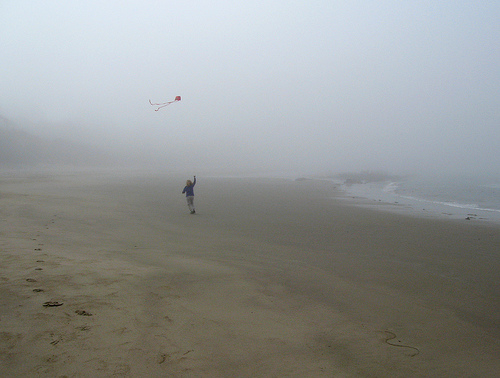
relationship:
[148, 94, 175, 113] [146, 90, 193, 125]
tail on kite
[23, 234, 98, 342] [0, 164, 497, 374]
marks on sand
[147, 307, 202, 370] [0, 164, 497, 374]
marks on sand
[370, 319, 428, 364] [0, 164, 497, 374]
marks on sand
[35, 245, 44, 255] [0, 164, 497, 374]
footstep in sand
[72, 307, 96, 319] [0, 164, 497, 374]
foot imprints in sand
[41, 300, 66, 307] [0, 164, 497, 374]
footstep in sand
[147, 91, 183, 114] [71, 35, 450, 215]
kite in air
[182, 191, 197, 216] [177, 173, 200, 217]
pants on person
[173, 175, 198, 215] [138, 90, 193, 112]
boy holding kite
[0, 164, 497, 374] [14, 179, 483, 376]
sand on ground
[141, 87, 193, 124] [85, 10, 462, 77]
kite in sky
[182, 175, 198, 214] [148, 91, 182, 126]
boy flying a kite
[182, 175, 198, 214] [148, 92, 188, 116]
boy flying a kite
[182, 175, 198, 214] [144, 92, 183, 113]
boy flying a kite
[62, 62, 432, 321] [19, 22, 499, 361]
weather on beach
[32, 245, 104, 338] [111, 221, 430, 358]
imprints on sand